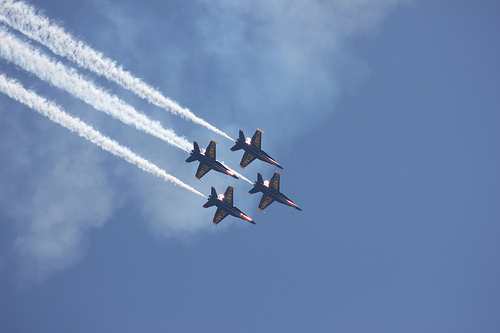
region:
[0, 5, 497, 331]
A blue sky filled with airplanes.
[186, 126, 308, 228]
Four planes in the sky.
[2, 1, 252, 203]
Smoke coming from airplanes.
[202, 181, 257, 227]
One airplane in the sky.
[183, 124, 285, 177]
Two planes next to each other.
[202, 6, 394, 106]
White smoke in the sky.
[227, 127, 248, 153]
The tail of an airplane.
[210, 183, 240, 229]
The wings of an airplane.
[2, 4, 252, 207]
White smoke in the sky.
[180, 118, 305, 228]
Four planes facing right.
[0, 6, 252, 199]
smoke trails from jets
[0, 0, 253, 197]
white smoke trails from jets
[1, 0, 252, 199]
three smoke traiks from fighter jets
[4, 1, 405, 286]
white clouds in blue sky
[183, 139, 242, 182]
fighter jet in the sky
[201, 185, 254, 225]
fighter jet in the sky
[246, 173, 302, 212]
fighter jet in the sky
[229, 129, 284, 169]
fighter jet in the sky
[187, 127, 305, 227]
four jets flying in the sky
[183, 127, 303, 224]
four fighter jets flying in a pattern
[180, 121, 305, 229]
Four blue airplanes in the sky.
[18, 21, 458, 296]
Air show for the public.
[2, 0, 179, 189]
Airplanes leaving tracks in the sky.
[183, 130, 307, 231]
Four airplanes flying too close together.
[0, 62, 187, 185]
White clouds coming from airplanes' tails.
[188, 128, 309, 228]
Airplanes flying very fast.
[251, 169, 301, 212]
Yellow writing showing the words "Blue Angel"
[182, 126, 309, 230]
Skilled pilots flying these airplanes.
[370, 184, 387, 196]
part of the sky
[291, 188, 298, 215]
part of a plane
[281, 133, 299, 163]
part of a cloud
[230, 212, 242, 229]
edge of a plane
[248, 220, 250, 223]
part of a plane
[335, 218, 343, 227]
part of the sky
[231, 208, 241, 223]
tip of a plane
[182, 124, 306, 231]
Four fighter jets flying in formation.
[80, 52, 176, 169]
Contrails in the skye from airplanes.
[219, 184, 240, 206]
Right wing of a fighter jet.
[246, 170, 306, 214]
Fighter jet with smoke coming out the back.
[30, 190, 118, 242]
Clouds in a blue sky.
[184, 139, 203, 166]
Tail of a fighter jet.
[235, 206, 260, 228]
Nose of a fighter jet.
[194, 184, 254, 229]
Fighter jet with smoke coming out the back.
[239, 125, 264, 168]
Both wings of a fighter jet.